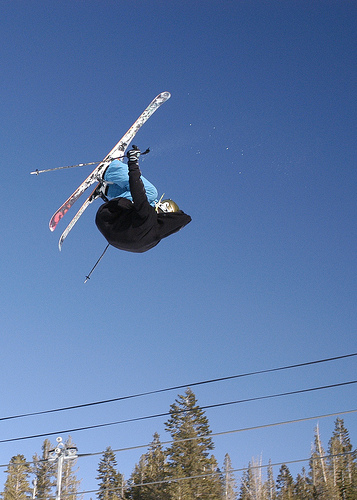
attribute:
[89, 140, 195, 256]
person — upside down, skiing, one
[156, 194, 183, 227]
helmet — gold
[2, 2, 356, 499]
sky — bright blue, outdoors, winter, day, clear, daytime, cloudless, blue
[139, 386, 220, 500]
tree — tall, pine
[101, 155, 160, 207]
pants — blue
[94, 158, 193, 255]
jacket — heavy, black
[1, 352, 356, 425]
wire — telephone, electrical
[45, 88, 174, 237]
ski — white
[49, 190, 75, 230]
graphic — pink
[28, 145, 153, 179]
ski pole — red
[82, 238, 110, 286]
ski pole — black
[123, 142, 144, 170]
glove — black